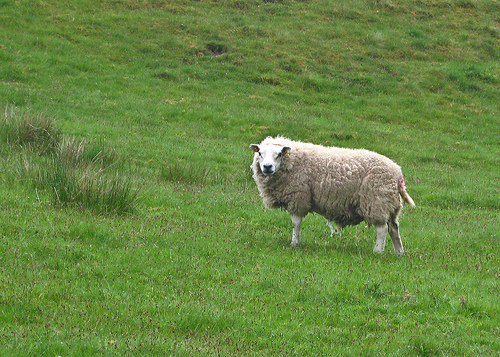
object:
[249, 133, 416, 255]
animal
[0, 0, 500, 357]
field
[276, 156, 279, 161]
eye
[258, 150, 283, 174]
face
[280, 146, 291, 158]
left ear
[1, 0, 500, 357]
grass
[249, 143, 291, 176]
head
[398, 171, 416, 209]
tail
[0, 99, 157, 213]
weeds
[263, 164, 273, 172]
nose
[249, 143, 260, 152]
ear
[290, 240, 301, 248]
front foot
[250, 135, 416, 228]
wool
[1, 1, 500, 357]
ground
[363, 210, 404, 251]
legs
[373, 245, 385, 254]
foot